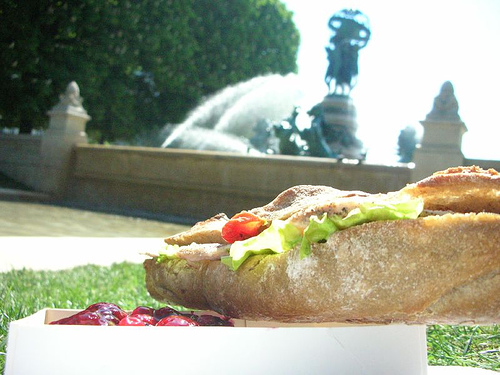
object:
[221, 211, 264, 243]
tomato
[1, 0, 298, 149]
tree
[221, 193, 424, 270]
lettuce leaf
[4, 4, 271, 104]
dense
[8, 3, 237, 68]
green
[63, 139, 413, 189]
curved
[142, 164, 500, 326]
sandwich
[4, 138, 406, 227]
beige wall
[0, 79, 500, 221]
columns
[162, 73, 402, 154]
ovals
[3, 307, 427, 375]
box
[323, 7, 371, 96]
figures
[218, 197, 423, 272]
lettuce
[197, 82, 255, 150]
water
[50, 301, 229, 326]
sauce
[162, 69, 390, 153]
fountain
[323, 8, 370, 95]
statue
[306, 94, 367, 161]
pillar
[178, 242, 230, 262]
meat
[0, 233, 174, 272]
path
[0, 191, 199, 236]
grass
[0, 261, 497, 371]
grass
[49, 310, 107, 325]
berries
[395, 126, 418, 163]
figures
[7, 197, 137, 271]
white reflection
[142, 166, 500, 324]
bread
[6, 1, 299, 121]
leaves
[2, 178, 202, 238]
floor